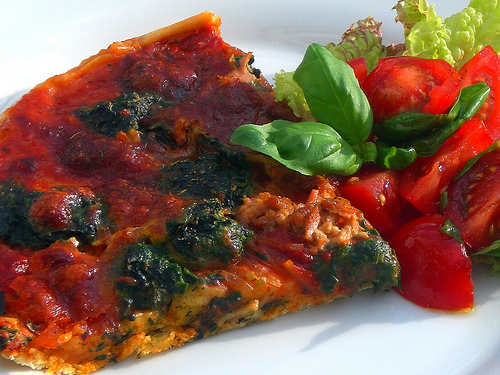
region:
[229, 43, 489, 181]
Basil leaves on the food.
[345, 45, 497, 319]
Cherry tomatoes on the plate.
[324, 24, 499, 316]
Cherry tomatoes cut in half.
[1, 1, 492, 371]
White plate on which the food sits.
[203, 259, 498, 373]
Shadow from the food.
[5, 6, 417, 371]
Crust of the pizza.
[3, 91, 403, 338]
Spinach in the pizza.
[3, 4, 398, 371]
Tomato sauce on the pizza.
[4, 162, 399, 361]
Cheese on the pizza.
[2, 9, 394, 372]
Spices on the pizza.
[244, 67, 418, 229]
green leaves on food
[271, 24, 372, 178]
green leaves on food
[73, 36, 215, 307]
A slice of pizza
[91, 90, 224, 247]
A slice of pizza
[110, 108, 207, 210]
A slice of pizza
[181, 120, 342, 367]
A slice of pizza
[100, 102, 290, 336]
A slice of pizza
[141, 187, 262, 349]
A slice of pizza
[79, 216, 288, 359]
A slice of pizza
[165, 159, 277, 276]
A slice of pizza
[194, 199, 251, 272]
A slice of pizza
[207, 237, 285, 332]
A slice of pizza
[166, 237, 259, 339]
A slice of pizza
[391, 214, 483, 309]
Red tomato on the side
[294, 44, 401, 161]
Green leaves with veggies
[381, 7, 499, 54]
Green lettuce behind tomato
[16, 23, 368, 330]
Slice of pizza on white surface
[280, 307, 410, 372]
Shadows of veggies being cast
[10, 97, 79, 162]
red tomato sauce on pizza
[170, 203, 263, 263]
Green spinach on tomato sauce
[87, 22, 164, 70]
Golden crust on slice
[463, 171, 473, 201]
Seeds of tomato within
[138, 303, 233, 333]
Melted cheese on slice